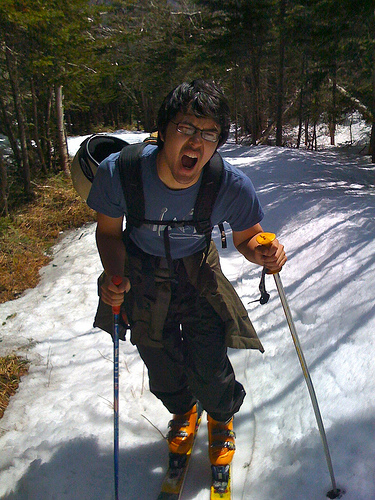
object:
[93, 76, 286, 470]
person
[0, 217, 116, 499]
snow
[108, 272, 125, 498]
ski rod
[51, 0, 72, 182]
tree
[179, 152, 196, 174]
open mouth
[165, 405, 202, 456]
orange boots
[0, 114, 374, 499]
ground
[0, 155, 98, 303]
grass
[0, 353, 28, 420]
brown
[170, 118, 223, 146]
glasses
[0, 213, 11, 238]
green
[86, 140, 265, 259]
blue shirt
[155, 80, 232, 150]
dark hair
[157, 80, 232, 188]
head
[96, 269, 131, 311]
right hand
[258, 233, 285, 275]
left hand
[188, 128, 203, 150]
nose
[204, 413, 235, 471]
left foot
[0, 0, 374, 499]
picture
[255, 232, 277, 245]
yellow tip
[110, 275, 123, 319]
red top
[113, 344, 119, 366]
coloured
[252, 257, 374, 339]
shadow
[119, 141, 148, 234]
straps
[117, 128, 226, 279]
pack